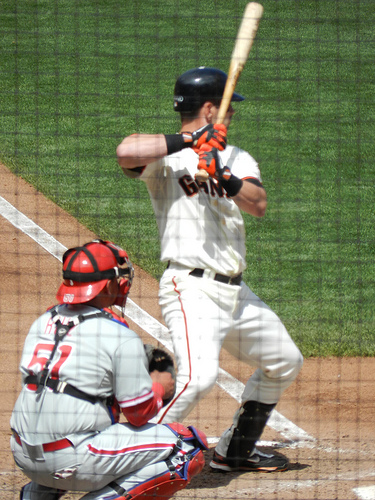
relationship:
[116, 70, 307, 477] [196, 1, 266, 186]
batter holding bat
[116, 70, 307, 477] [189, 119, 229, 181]
batter wearing gloves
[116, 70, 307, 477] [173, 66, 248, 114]
batter wearing helmet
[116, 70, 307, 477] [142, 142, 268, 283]
batter wearing shirt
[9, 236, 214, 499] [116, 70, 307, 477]
catcher behind batter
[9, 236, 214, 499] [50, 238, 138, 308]
catcher wearing cap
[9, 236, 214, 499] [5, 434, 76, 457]
catcher wearing belt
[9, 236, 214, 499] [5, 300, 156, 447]
catcher wearing shirt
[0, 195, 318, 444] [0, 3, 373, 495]
line on field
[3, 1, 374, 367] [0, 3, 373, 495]
grass on field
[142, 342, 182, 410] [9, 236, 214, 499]
mitt for catcher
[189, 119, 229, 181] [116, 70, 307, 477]
gloves are for batter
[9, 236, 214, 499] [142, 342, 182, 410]
catcher has mitt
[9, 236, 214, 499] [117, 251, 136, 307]
catcher has mask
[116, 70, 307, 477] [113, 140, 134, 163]
batter has elbow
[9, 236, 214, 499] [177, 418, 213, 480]
catcher has knee guard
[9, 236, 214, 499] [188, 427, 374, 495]
catcher facing moud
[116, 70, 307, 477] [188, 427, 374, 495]
batter of moud